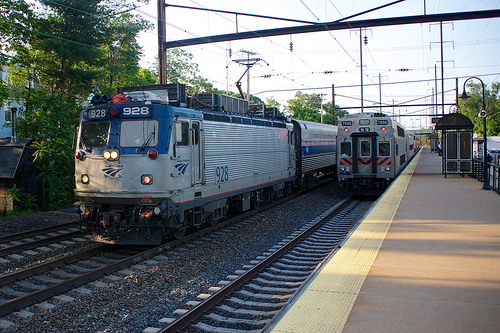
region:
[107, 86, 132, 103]
Red sign on the train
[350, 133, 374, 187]
door on the front of the train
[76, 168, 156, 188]
lights on the train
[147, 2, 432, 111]
electric lines over the train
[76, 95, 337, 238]
white and blue train on track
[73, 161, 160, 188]
headlights are lit on train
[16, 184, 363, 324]
brown metal train tracks with gravel under them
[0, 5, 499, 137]
electrical wires above les miserable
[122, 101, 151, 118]
train is number 928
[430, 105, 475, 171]
trainstation shelter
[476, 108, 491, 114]
round white and black sign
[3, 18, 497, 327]
daytime railway scene with two approaching trains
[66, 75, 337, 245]
grey and blue train on tracks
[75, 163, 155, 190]
two round lit headlights on train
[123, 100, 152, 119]
number 926 on front of train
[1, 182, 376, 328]
metal train tracks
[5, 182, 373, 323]
gray gravel in between train tracks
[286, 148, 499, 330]
concrete platform at station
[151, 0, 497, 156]
electrical wires above trains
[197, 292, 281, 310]
wooden board on tracks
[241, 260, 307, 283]
wooden board on tracks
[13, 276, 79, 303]
wooden board on tracks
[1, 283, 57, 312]
wooden board on tracks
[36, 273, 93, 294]
wooden board on tracks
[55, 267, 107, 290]
wooden board on tracks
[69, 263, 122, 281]
wooden board on tracks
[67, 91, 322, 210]
silver and blue light rail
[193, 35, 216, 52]
white clouds in blue sky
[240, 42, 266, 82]
white clouds in blue sky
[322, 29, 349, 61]
white clouds in blue sky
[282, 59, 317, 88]
white clouds in blue sky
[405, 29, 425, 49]
white clouds in blue sky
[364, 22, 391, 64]
white clouds in blue sky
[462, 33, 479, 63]
white clouds in blue sky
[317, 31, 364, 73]
white clouds in blue sky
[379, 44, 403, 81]
white clouds in blue sky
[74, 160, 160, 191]
two round lit headlights on train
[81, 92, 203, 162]
blue front to grey train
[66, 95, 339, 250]
long grey train with blue front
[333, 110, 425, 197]
second grey train with red lit lights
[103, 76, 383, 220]
Trains on the tracks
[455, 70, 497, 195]
Light pole near tracks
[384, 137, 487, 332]
Train platform near the tracks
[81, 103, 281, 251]
this is a passenger train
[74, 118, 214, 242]
the train is blue and gray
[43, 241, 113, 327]
these are train tracks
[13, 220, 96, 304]
the tracks are brown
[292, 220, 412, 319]
this is a platform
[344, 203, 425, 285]
this is a line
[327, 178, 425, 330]
the line is yellow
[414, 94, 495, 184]
this is a waiting area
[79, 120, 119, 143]
window in front of train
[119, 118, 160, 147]
window in front of train